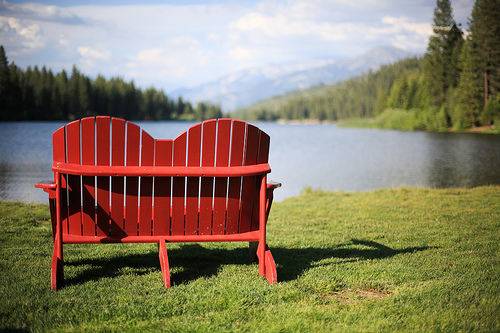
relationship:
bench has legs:
[29, 107, 293, 296] [34, 239, 291, 290]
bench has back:
[29, 107, 293, 296] [61, 160, 267, 211]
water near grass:
[2, 120, 500, 195] [3, 198, 499, 328]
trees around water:
[3, 30, 500, 125] [2, 120, 500, 195]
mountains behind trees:
[237, 50, 430, 123] [3, 30, 500, 125]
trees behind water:
[3, 30, 500, 125] [2, 120, 500, 195]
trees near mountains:
[3, 30, 500, 125] [237, 50, 430, 123]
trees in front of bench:
[3, 30, 500, 125] [29, 107, 293, 296]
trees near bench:
[3, 30, 500, 125] [29, 107, 293, 296]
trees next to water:
[3, 30, 500, 125] [2, 120, 500, 195]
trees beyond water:
[3, 30, 500, 125] [2, 120, 500, 195]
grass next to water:
[3, 198, 499, 328] [2, 120, 500, 195]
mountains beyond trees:
[237, 50, 430, 123] [3, 30, 500, 125]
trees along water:
[3, 30, 500, 125] [2, 120, 500, 195]